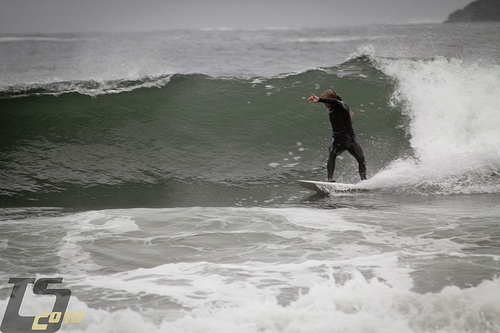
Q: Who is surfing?
A: A man.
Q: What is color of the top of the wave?
A: White.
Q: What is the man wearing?
A: A wet suit.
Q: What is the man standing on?
A: A surfboard.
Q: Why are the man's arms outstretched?
A: To balance.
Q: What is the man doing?
A: Surfing.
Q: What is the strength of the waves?
A: Strong.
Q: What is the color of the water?
A: Green.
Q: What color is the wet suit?
A: Black.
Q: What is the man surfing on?
A: Large waves.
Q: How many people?
A: One.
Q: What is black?
A: Wetsuit.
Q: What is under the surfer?
A: Board.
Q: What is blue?
A: Sky.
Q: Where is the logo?
A: Bottom left.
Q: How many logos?
A: One.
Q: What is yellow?
A: Logo.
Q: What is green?
A: Ocean.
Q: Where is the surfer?
A: In the water.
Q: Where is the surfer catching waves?
A: Ocean.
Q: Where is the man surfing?
A: Ocean.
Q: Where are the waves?
A: In water.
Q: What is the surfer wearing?
A: Wetsuit.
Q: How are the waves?
A: Large.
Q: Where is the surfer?
A: In the Ocean.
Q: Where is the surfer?
A: Surfboard.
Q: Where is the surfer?
A: Ocean wave.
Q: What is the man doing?
A: Surfing.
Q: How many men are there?
A: 1.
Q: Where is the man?
A: In the water.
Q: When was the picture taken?
A: Daytime.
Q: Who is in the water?
A: The man.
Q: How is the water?
A: Wavy.